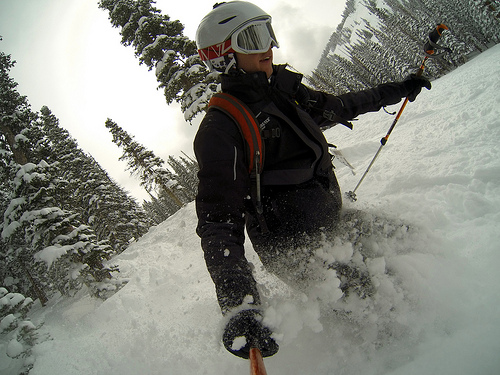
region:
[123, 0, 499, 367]
Person in the snow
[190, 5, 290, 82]
Ski helmet on a person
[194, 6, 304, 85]
A person wearing goggles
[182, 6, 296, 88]
A white helmet and ski goggles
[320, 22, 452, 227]
A downhill ski pole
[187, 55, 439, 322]
A winter ski jacket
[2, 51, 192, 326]
Snow covered pine trees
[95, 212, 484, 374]
Snow spraying up from the ground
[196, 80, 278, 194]
Orange strap on shoulder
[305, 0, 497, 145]
Person holding a ski pole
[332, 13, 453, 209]
ski pole being held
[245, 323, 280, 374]
ski pole being held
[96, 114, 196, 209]
tree covered in snow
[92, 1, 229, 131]
tree covered in snow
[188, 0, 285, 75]
white helmet and goggles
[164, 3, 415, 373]
person wearing a helmet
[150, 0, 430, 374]
person wearing a black jacket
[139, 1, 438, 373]
person wearing goggles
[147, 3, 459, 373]
person holding ski poles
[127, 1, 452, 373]
person in the snow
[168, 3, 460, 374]
person kicking up snow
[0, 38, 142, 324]
a group of pine trees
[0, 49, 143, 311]
snow covered pine trees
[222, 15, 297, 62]
goggles on a skier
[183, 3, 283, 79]
helmet on a skier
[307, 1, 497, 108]
a row of pine trees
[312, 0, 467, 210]
ski pole in the left hand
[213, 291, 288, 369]
glove on the right hand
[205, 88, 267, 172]
a red and black strap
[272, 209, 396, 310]
airborne snow in front of skier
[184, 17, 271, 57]
person wears white helmet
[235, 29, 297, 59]
person wears shiny goggles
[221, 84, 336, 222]
person has brown jacket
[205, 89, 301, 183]
red strap from backpack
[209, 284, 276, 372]
person has black winter gloves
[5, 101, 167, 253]
tall pine trees behind person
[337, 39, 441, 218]
black and orange ski poles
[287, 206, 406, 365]
person makes tracks in snow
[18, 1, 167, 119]
sky is grey and cloudy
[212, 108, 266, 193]
white stripes on jacket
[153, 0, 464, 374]
a person skiing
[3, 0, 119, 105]
the sky is gray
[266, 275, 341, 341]
snow in the air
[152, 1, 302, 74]
the person wearing a helmet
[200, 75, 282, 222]
the red book bag strap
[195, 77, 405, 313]
the person wearing a jacket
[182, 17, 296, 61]
the white goggles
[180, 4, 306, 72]
the helmet is white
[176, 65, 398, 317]
the jacket is black